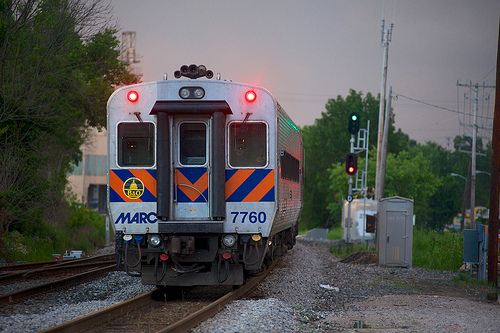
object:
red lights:
[127, 88, 139, 104]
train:
[104, 63, 306, 290]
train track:
[35, 255, 284, 331]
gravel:
[5, 237, 348, 332]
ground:
[301, 262, 499, 329]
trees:
[0, 0, 64, 259]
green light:
[350, 113, 359, 122]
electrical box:
[460, 227, 484, 266]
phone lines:
[460, 81, 471, 151]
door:
[162, 108, 219, 224]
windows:
[228, 121, 272, 171]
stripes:
[241, 169, 276, 202]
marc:
[111, 210, 160, 226]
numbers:
[230, 210, 271, 225]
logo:
[122, 176, 146, 200]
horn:
[172, 64, 214, 80]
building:
[67, 109, 106, 210]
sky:
[0, 0, 500, 153]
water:
[314, 294, 500, 332]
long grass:
[413, 228, 468, 273]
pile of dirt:
[335, 249, 379, 265]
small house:
[379, 195, 417, 271]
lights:
[178, 87, 191, 100]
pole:
[371, 21, 394, 204]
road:
[295, 227, 331, 240]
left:
[7, 132, 40, 217]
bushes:
[69, 201, 105, 250]